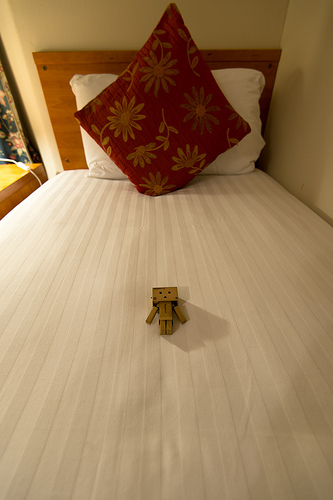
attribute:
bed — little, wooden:
[2, 48, 331, 497]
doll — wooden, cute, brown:
[147, 281, 190, 341]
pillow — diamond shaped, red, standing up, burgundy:
[73, 4, 253, 198]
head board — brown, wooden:
[30, 40, 282, 176]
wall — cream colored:
[2, 1, 333, 225]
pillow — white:
[68, 64, 268, 181]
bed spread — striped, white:
[0, 168, 333, 499]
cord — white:
[1, 157, 43, 187]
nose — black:
[161, 293, 170, 301]